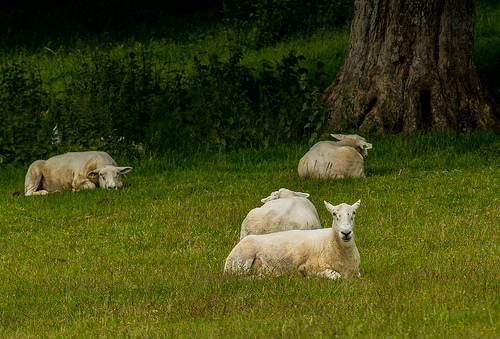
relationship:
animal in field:
[23, 151, 132, 196] [41, 155, 496, 331]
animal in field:
[222, 199, 364, 281] [1, 75, 496, 337]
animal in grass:
[238, 188, 321, 241] [316, 205, 334, 227]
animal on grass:
[298, 134, 373, 178] [1, 128, 497, 336]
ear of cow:
[320, 197, 335, 216] [220, 196, 370, 281]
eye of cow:
[351, 206, 356, 216] [220, 196, 370, 281]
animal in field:
[220, 200, 362, 285] [0, 28, 499, 339]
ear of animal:
[350, 191, 362, 208] [220, 196, 369, 290]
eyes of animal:
[327, 201, 357, 222] [229, 207, 380, 321]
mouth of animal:
[103, 182, 119, 195] [33, 148, 141, 210]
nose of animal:
[107, 182, 118, 187] [33, 148, 141, 210]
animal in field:
[298, 134, 373, 178] [5, 143, 498, 333]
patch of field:
[4, 130, 494, 339] [0, 28, 499, 339]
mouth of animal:
[341, 225, 353, 244] [23, 151, 132, 196]